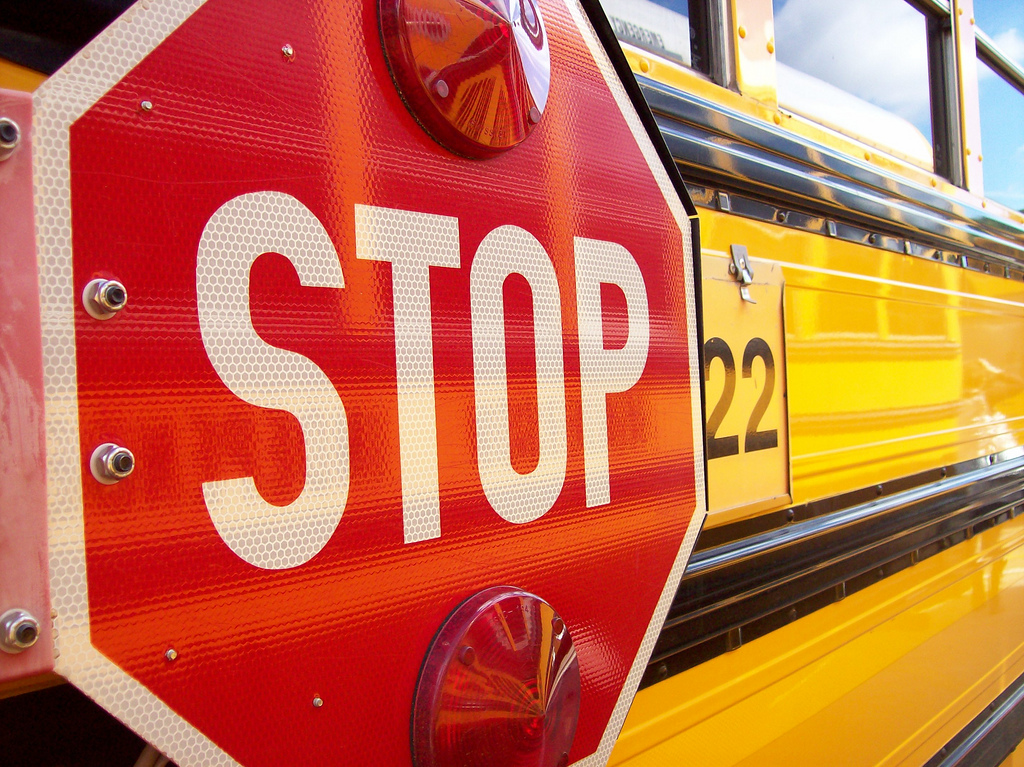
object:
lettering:
[195, 191, 649, 570]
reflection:
[695, 204, 1023, 529]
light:
[410, 585, 582, 767]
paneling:
[632, 76, 1024, 270]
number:
[704, 337, 778, 460]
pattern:
[232, 224, 278, 238]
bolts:
[729, 244, 757, 304]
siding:
[638, 81, 1024, 265]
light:
[377, 1, 550, 161]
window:
[592, 0, 1021, 218]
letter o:
[469, 224, 567, 524]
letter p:
[573, 236, 650, 509]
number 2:
[742, 337, 778, 453]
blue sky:
[647, 0, 1024, 218]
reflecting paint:
[28, 0, 709, 767]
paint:
[603, 513, 1022, 767]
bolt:
[83, 278, 129, 320]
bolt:
[90, 443, 136, 485]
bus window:
[774, 0, 954, 181]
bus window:
[974, 34, 1023, 217]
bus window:
[599, 0, 711, 76]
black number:
[704, 337, 740, 460]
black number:
[742, 337, 777, 451]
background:
[701, 277, 791, 513]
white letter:
[354, 204, 460, 544]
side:
[600, 0, 1021, 763]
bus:
[0, 0, 1024, 767]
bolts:
[82, 278, 136, 485]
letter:
[195, 191, 348, 571]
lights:
[375, 0, 580, 767]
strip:
[682, 454, 1024, 583]